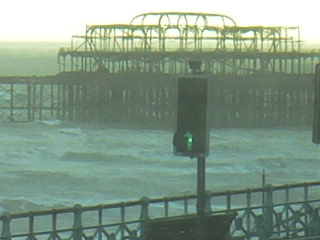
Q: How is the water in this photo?
A: Choppy.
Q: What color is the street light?
A: Green.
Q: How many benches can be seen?
A: One.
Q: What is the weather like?
A: Rainy.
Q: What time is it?
A: Afternoon.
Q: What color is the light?
A: Green.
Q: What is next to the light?
A: Water.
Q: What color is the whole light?
A: Black.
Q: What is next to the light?
A: Bench.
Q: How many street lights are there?
A: One.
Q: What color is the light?
A: Green.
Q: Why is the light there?
A: To control traffic.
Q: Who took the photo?
A: The photographer.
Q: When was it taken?
A: In the afternoon.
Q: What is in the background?
A: A pier.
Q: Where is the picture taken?
A: By the ocean.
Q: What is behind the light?
A: A fence.